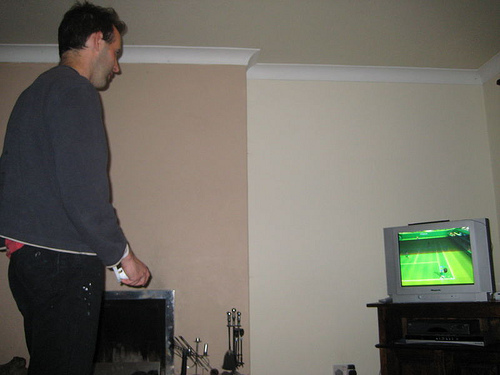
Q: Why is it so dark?
A: Dim lights.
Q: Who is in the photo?
A: The man.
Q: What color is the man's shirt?
A: Gray.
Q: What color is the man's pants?
A: Black.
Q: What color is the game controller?
A: White.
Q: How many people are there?
A: One.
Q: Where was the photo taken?
A: In the living room.